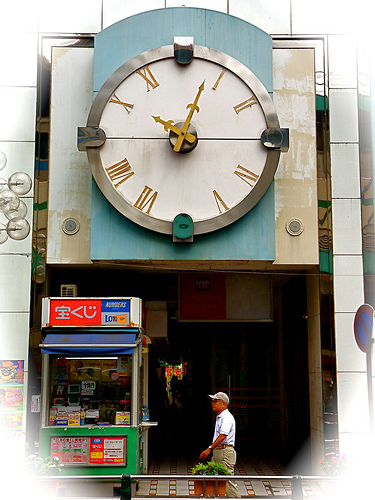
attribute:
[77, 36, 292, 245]
clock — wide, gold, round, silver, white, large, big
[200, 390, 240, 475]
man — walking, standing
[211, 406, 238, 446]
shirt — blue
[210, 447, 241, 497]
pants — tan, khaki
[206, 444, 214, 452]
watch — gold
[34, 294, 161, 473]
vendor stand — colorful, green, red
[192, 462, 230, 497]
plants — green, dark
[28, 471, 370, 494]
railing — metal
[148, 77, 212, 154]
hands — gold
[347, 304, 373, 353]
traffic sign — blue